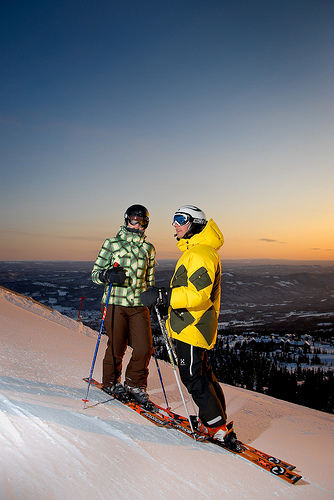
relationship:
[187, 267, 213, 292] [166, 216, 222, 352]
pocket on jacket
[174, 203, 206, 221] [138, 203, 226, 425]
helmet on man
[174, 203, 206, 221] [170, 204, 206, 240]
helmet on head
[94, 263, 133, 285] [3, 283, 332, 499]
hand on slope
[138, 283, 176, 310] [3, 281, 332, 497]
hand on mountain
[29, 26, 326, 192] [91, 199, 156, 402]
sky behind skiers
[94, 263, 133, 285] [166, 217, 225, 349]
hand wearing coat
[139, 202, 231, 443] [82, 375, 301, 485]
people on skis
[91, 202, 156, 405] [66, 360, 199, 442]
people on skis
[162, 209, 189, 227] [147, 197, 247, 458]
goggles on person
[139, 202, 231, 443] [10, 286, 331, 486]
people standing on snow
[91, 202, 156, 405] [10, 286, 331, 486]
people standing on snow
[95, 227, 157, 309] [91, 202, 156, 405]
coat on people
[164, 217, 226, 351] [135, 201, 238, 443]
coat on man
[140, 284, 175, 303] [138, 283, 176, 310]
glove on hand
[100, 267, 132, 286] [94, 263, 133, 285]
glove on hand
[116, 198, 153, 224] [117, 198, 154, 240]
helmet on head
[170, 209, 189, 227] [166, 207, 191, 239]
goggles on face